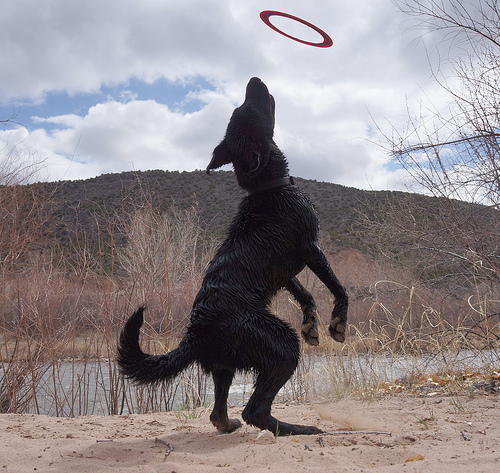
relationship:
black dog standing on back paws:
[112, 78, 351, 438] [207, 417, 324, 434]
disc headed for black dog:
[259, 9, 332, 48] [112, 78, 351, 438]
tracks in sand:
[0, 417, 418, 447] [3, 386, 498, 471]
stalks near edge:
[2, 278, 499, 414] [3, 367, 498, 416]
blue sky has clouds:
[0, 0, 500, 206] [5, 3, 495, 209]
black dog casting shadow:
[112, 78, 351, 438] [56, 427, 272, 471]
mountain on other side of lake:
[4, 170, 498, 322] [2, 347, 499, 433]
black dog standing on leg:
[112, 78, 351, 438] [238, 311, 324, 438]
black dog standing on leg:
[112, 78, 351, 438] [205, 363, 244, 433]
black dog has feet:
[112, 78, 351, 438] [325, 317, 349, 344]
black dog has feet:
[112, 78, 351, 438] [300, 320, 323, 348]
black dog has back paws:
[112, 78, 351, 438] [214, 417, 242, 434]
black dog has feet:
[112, 78, 351, 438] [273, 423, 323, 436]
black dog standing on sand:
[112, 78, 351, 438] [3, 386, 498, 471]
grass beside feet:
[0, 213, 495, 421] [273, 423, 323, 436]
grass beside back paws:
[0, 213, 495, 421] [214, 417, 242, 434]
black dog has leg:
[112, 78, 351, 438] [238, 311, 324, 438]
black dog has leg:
[112, 78, 351, 438] [208, 368, 243, 435]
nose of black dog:
[244, 74, 262, 88] [112, 78, 351, 438]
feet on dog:
[300, 320, 323, 348] [107, 83, 360, 470]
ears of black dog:
[208, 140, 268, 180] [112, 78, 351, 438]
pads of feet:
[300, 317, 344, 345] [300, 320, 323, 348]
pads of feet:
[300, 317, 344, 345] [325, 317, 349, 344]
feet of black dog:
[300, 320, 323, 348] [112, 78, 351, 438]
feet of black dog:
[325, 317, 349, 344] [112, 78, 351, 438]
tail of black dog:
[112, 301, 188, 383] [112, 78, 351, 438]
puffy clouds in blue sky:
[4, 97, 389, 187] [4, 69, 231, 136]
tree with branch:
[355, 3, 483, 371] [355, 94, 498, 196]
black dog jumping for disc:
[112, 78, 351, 438] [259, 9, 332, 48]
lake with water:
[2, 347, 498, 417] [7, 349, 483, 416]